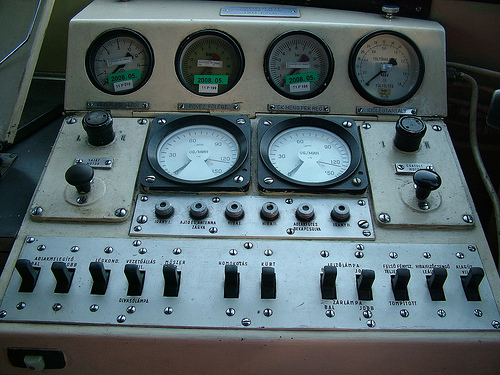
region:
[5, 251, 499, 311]
row of on/off switches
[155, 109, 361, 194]
two large gauges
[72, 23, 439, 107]
row of four gauges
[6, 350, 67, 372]
small white button on bottom of machine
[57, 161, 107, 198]
screw shaped knob on left side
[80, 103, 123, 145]
large knob on left side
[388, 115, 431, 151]
large knob on right side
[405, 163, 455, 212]
screw shaped knob on right side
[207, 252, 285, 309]
two on/off swtiches in the middle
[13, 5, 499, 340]
panel of gauges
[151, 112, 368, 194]
pair of dial instruments in console center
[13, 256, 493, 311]
row of black switches on console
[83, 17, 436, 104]
a row of four gauges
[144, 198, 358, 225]
row of six indicator lights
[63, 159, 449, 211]
two smooth black plunger buttons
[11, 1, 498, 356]
black and white control console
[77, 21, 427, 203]
six round faced dial gauges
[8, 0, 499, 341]
out of date vehicular control panel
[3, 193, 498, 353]
rows of switches and indicators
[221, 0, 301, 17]
control console information label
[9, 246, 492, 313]
twelve black switches in neutral position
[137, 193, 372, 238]
six audio jacks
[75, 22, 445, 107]
four different kinds of gauges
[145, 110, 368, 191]
two large, round gauges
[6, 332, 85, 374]
a power switch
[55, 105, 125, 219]
two different kinds of knobs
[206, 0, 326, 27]
a metal plate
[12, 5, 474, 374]
an machine with analog dials and gauges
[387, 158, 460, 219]
a black knob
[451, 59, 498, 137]
electrical cords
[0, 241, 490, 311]
a row of black knobs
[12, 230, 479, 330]
a silver panel of knobs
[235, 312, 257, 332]
the screw is silver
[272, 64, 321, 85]
green sticker on the glass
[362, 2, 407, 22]
silver knob on top of device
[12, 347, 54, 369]
a white button on the bottom left front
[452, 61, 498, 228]
a silver long pipe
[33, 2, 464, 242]
the device is white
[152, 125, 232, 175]
numbers on a white face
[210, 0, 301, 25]
a small plate with words on it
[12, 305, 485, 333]
row of silver bolts on control panel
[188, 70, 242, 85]
green sticker on front of gauge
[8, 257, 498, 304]
row of black control switches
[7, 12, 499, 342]
a control panel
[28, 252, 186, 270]
red writing above black switches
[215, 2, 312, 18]
silver panel on top of control panel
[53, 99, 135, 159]
large black control knob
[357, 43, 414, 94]
black needle in control gauge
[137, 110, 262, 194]
white gauge with black trim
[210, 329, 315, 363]
black dirt specks on front of control panel